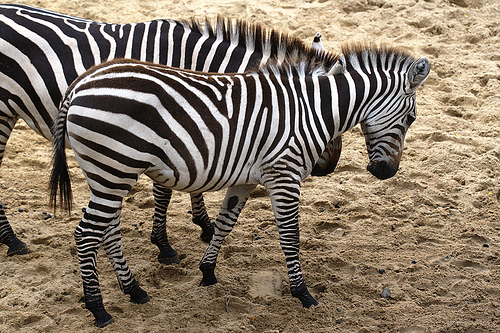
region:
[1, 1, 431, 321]
Two zebras walking on the sand.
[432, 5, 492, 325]
The sand is tan colored.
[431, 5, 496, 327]
The sand has many foot prints on it.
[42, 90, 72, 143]
Zebra tail has smaller stripes.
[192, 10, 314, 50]
The zebra's mane stands straight on its back.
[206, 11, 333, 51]
The zebra's mane is striped.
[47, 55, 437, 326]
The zebra's coat is striped in black and white.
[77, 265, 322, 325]
The zebra's paws are all black.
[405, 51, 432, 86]
The zebra's ear is pointing up.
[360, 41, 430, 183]
Zebra looking at the sand.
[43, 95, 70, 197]
The tail of the zebra in the front.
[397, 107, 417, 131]
The eye of the zebra in the front.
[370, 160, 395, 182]
The nose of the zebra in the front.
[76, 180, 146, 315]
The back legs of the zebra in the front.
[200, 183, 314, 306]
The front legs of the zebra in the front.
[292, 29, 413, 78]
The mane of the zebra in the front.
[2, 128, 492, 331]
The sand the zebras are standing on.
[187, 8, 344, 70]
The mane of the zebra in the back.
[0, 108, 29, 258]
The back leg of the zebra in the back.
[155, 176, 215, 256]
The front legs of the zebra in the back.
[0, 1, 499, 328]
Sand below the zebras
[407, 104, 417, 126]
The right eye of the zebra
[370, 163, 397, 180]
The nose of the zebra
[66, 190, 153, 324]
The back legs of the zebra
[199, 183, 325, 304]
The front legs of the zebra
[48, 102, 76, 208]
The tail fo the zebra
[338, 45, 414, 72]
The mane of the zebra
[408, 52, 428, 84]
The right ear of the zebra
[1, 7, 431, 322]
Two zebras in the sand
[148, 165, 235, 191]
The stomach of the zebra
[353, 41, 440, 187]
the head of a zebra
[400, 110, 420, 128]
the eye of a zebra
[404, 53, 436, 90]
the ear of a zebra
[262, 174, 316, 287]
the leg of a zebra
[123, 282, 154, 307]
the hoof of a zebra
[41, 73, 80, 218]
the tail of a zebra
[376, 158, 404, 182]
the nose of a zebra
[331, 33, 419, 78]
the mane of a zebra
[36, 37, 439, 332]
a black and white zebra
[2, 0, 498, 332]
brown sand on the ground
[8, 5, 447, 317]
Two zebras close together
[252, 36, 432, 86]
spiky mane on top of zebra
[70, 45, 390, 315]
the white and black stripes of the zebra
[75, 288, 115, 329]
the black hooves of the zebra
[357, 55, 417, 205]
the long snot of the zebra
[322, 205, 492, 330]
sand for the zebras to walk in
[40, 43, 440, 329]
a small young zebra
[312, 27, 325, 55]
a black and white bird by the zebras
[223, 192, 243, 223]
a black splotch on the zebras leg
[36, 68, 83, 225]
the shorter tail of the zebra